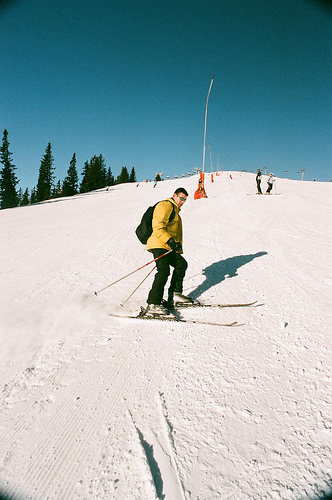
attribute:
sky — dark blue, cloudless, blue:
[0, 1, 330, 209]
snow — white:
[0, 168, 330, 499]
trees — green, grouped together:
[1, 123, 165, 211]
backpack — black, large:
[136, 203, 155, 244]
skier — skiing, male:
[143, 184, 193, 314]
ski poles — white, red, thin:
[92, 239, 174, 308]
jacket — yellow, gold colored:
[148, 198, 184, 254]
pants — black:
[146, 247, 187, 305]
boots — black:
[143, 290, 195, 322]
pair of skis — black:
[111, 297, 261, 330]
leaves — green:
[1, 127, 165, 209]